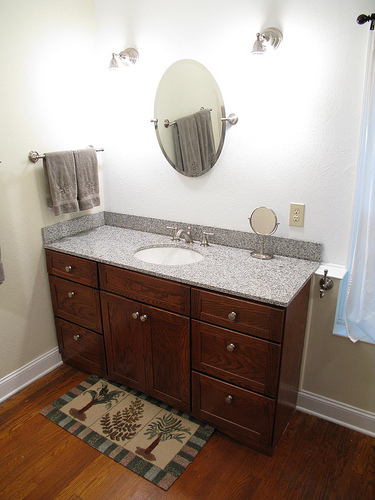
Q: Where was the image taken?
A: It was taken at the bathroom.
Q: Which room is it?
A: It is a bathroom.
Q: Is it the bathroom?
A: Yes, it is the bathroom.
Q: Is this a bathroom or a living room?
A: It is a bathroom.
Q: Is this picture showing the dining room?
A: No, the picture is showing the bathroom.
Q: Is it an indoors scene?
A: Yes, it is indoors.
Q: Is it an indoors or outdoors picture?
A: It is indoors.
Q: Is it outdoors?
A: No, it is indoors.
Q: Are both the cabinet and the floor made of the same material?
A: Yes, both the cabinet and the floor are made of wood.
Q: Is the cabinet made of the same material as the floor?
A: Yes, both the cabinet and the floor are made of wood.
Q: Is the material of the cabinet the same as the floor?
A: Yes, both the cabinet and the floor are made of wood.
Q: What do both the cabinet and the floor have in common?
A: The material, both the cabinet and the floor are wooden.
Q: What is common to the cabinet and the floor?
A: The material, both the cabinet and the floor are wooden.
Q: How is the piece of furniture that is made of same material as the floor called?
A: The piece of furniture is a cabinet.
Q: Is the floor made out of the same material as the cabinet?
A: Yes, both the floor and the cabinet are made of wood.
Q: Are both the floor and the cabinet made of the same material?
A: Yes, both the floor and the cabinet are made of wood.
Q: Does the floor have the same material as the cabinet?
A: Yes, both the floor and the cabinet are made of wood.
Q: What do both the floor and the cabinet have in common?
A: The material, both the floor and the cabinet are wooden.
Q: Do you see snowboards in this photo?
A: No, there are no snowboards.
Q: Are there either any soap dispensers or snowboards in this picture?
A: No, there are no snowboards or soap dispensers.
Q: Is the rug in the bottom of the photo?
A: Yes, the rug is in the bottom of the image.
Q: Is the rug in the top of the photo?
A: No, the rug is in the bottom of the image.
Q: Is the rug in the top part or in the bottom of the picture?
A: The rug is in the bottom of the image.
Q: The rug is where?
A: The rug is on the floor.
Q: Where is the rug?
A: The rug is on the floor.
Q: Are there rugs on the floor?
A: Yes, there is a rug on the floor.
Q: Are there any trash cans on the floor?
A: No, there is a rug on the floor.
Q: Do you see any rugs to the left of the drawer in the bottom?
A: Yes, there is a rug to the left of the drawer.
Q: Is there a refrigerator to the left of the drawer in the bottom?
A: No, there is a rug to the left of the drawer.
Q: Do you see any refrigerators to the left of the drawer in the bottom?
A: No, there is a rug to the left of the drawer.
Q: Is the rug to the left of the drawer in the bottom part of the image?
A: Yes, the rug is to the left of the drawer.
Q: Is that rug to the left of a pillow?
A: No, the rug is to the left of the drawer.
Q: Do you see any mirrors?
A: Yes, there is a mirror.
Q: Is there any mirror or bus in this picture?
A: Yes, there is a mirror.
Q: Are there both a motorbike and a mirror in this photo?
A: No, there is a mirror but no motorcycles.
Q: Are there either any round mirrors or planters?
A: Yes, there is a round mirror.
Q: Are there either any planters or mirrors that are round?
A: Yes, the mirror is round.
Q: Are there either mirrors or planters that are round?
A: Yes, the mirror is round.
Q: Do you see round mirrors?
A: Yes, there is a round mirror.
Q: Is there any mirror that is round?
A: Yes, there is a mirror that is round.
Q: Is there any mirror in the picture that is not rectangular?
A: Yes, there is a round mirror.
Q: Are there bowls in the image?
A: No, there are no bowls.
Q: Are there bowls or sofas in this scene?
A: No, there are no bowls or sofas.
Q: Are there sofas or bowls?
A: No, there are no bowls or sofas.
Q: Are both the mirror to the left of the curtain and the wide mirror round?
A: Yes, both the mirror and the mirror are round.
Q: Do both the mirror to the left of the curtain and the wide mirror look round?
A: Yes, both the mirror and the mirror are round.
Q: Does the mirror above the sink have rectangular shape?
A: No, the mirror is round.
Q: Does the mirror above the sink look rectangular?
A: No, the mirror is round.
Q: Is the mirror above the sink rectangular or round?
A: The mirror is round.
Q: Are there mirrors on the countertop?
A: Yes, there is a mirror on the countertop.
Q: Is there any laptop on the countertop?
A: No, there is a mirror on the countertop.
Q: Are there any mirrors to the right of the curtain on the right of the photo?
A: No, the mirror is to the left of the curtain.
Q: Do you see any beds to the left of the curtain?
A: No, there is a mirror to the left of the curtain.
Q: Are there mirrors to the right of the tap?
A: Yes, there is a mirror to the right of the tap.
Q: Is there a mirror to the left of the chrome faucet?
A: No, the mirror is to the right of the faucet.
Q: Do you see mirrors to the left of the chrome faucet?
A: No, the mirror is to the right of the faucet.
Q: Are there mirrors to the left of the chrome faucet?
A: No, the mirror is to the right of the faucet.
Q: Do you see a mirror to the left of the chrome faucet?
A: No, the mirror is to the right of the faucet.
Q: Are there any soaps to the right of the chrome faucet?
A: No, there is a mirror to the right of the tap.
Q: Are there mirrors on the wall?
A: Yes, there is a mirror on the wall.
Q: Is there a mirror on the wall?
A: Yes, there is a mirror on the wall.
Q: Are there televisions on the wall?
A: No, there is a mirror on the wall.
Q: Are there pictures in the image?
A: No, there are no pictures.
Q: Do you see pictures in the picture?
A: No, there are no pictures.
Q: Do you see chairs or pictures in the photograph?
A: No, there are no pictures or chairs.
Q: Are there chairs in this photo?
A: No, there are no chairs.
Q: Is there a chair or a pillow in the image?
A: No, there are no chairs or pillows.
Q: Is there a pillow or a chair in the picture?
A: No, there are no chairs or pillows.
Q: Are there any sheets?
A: No, there are no sheets.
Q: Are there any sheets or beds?
A: No, there are no sheets or beds.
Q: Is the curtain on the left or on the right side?
A: The curtain is on the right of the image.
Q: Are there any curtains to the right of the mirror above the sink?
A: Yes, there is a curtain to the right of the mirror.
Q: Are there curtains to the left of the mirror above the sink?
A: No, the curtain is to the right of the mirror.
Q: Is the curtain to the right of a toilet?
A: No, the curtain is to the right of a mirror.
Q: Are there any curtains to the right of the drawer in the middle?
A: Yes, there is a curtain to the right of the drawer.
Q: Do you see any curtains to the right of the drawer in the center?
A: Yes, there is a curtain to the right of the drawer.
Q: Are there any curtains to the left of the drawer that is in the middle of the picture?
A: No, the curtain is to the right of the drawer.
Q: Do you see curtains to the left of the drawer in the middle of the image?
A: No, the curtain is to the right of the drawer.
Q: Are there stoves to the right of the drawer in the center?
A: No, there is a curtain to the right of the drawer.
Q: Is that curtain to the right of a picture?
A: No, the curtain is to the right of the drawer.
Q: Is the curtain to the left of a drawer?
A: No, the curtain is to the right of a drawer.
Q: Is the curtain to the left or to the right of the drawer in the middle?
A: The curtain is to the right of the drawer.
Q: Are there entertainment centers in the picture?
A: No, there are no entertainment centers.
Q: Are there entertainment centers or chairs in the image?
A: No, there are no entertainment centers or chairs.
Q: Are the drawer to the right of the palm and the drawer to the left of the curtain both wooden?
A: Yes, both the drawer and the drawer are wooden.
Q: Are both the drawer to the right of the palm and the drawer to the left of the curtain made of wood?
A: Yes, both the drawer and the drawer are made of wood.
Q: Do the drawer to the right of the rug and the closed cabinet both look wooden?
A: Yes, both the drawer and the cabinet are wooden.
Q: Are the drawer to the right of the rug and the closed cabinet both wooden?
A: Yes, both the drawer and the cabinet are wooden.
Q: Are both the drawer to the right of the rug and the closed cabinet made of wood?
A: Yes, both the drawer and the cabinet are made of wood.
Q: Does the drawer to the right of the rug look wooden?
A: Yes, the drawer is wooden.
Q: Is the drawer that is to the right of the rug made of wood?
A: Yes, the drawer is made of wood.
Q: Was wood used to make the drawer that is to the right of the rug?
A: Yes, the drawer is made of wood.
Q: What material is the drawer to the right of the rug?
A: The drawer is made of wood.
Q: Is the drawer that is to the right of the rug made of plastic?
A: No, the drawer is made of wood.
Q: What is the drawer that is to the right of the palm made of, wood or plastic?
A: The drawer is made of wood.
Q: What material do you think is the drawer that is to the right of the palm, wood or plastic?
A: The drawer is made of wood.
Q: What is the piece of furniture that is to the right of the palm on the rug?
A: The piece of furniture is a drawer.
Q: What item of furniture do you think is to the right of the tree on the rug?
A: The piece of furniture is a drawer.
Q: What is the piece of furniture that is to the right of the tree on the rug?
A: The piece of furniture is a drawer.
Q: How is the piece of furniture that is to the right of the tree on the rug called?
A: The piece of furniture is a drawer.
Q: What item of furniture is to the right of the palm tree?
A: The piece of furniture is a drawer.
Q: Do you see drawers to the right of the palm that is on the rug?
A: Yes, there is a drawer to the right of the palm tree.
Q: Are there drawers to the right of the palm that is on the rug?
A: Yes, there is a drawer to the right of the palm tree.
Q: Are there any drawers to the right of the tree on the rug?
A: Yes, there is a drawer to the right of the palm tree.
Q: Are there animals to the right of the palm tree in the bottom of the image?
A: No, there is a drawer to the right of the palm.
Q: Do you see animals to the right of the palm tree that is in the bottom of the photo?
A: No, there is a drawer to the right of the palm.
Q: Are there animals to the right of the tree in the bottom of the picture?
A: No, there is a drawer to the right of the palm.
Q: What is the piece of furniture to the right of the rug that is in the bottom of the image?
A: The piece of furniture is a drawer.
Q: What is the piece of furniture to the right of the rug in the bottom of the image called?
A: The piece of furniture is a drawer.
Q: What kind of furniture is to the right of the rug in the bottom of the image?
A: The piece of furniture is a drawer.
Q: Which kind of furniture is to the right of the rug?
A: The piece of furniture is a drawer.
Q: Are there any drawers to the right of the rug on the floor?
A: Yes, there is a drawer to the right of the rug.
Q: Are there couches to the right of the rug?
A: No, there is a drawer to the right of the rug.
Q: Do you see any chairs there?
A: No, there are no chairs.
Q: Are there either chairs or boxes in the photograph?
A: No, there are no chairs or boxes.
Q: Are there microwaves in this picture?
A: No, there are no microwaves.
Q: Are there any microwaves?
A: No, there are no microwaves.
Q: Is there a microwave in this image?
A: No, there are no microwaves.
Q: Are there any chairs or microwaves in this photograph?
A: No, there are no microwaves or chairs.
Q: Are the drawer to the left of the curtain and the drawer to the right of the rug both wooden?
A: Yes, both the drawer and the drawer are wooden.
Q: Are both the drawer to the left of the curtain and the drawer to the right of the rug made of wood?
A: Yes, both the drawer and the drawer are made of wood.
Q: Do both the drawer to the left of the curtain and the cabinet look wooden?
A: Yes, both the drawer and the cabinet are wooden.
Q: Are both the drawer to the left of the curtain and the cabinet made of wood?
A: Yes, both the drawer and the cabinet are made of wood.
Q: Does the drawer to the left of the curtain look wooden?
A: Yes, the drawer is wooden.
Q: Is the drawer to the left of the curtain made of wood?
A: Yes, the drawer is made of wood.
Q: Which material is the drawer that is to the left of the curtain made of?
A: The drawer is made of wood.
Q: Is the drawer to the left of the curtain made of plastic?
A: No, the drawer is made of wood.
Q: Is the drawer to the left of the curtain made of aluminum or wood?
A: The drawer is made of wood.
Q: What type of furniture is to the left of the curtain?
A: The piece of furniture is a drawer.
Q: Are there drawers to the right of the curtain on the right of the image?
A: No, the drawer is to the left of the curtain.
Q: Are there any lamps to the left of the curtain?
A: No, there is a drawer to the left of the curtain.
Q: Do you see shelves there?
A: No, there are no shelves.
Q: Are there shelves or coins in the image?
A: No, there are no shelves or coins.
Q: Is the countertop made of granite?
A: Yes, the countertop is made of granite.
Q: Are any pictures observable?
A: No, there are no pictures.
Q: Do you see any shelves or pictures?
A: No, there are no pictures or shelves.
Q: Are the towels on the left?
A: Yes, the towels are on the left of the image.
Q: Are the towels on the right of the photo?
A: No, the towels are on the left of the image.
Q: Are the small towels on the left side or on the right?
A: The towels are on the left of the image.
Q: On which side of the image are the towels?
A: The towels are on the left of the image.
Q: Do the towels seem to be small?
A: Yes, the towels are small.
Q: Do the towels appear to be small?
A: Yes, the towels are small.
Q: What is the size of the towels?
A: The towels are small.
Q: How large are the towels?
A: The towels are small.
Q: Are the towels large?
A: No, the towels are small.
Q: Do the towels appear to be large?
A: No, the towels are small.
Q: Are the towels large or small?
A: The towels are small.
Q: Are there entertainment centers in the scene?
A: No, there are no entertainment centers.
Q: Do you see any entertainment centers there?
A: No, there are no entertainment centers.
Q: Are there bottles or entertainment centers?
A: No, there are no entertainment centers or bottles.